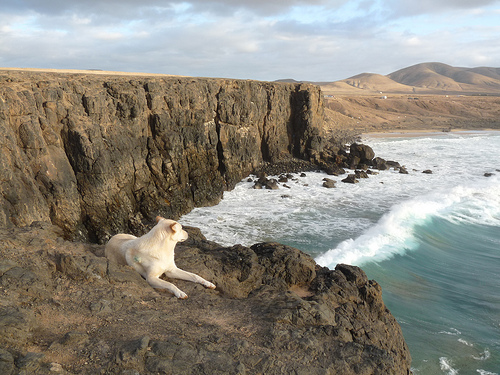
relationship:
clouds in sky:
[183, 29, 322, 58] [5, 0, 498, 80]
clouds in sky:
[307, 48, 397, 68] [5, 0, 498, 80]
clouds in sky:
[197, 4, 279, 24] [5, 0, 498, 80]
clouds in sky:
[234, 22, 375, 65] [5, 0, 498, 80]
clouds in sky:
[274, 25, 334, 67] [5, 0, 498, 80]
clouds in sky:
[141, 27, 240, 77] [5, 0, 498, 80]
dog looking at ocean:
[92, 210, 232, 308] [157, 119, 497, 373]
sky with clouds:
[5, 0, 498, 80] [173, 24, 350, 60]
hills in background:
[330, 51, 499, 101] [9, 46, 492, 113]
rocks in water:
[265, 141, 413, 186] [155, 130, 491, 371]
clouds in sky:
[6, 13, 467, 85] [0, 2, 492, 67]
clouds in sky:
[1, 2, 497, 78] [4, 6, 498, 86]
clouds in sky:
[0, 10, 490, 84] [0, 8, 494, 78]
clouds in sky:
[1, 2, 497, 78] [5, 0, 498, 80]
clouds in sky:
[1, 2, 497, 78] [0, 8, 494, 78]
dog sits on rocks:
[92, 210, 232, 308] [6, 220, 396, 372]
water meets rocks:
[155, 130, 491, 371] [248, 111, 422, 200]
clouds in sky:
[1, 2, 497, 78] [0, 2, 490, 74]